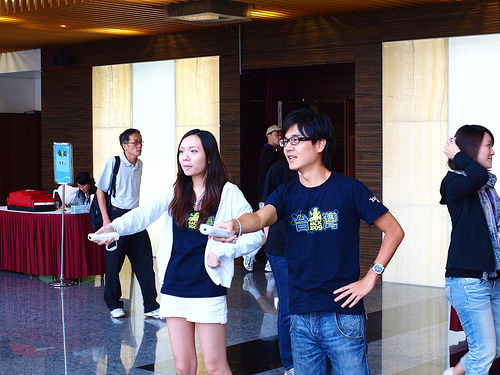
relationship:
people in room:
[59, 106, 499, 373] [2, 1, 500, 374]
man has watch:
[210, 106, 407, 373] [370, 260, 389, 274]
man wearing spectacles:
[210, 106, 407, 373] [281, 133, 326, 149]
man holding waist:
[210, 106, 407, 373] [282, 284, 372, 342]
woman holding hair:
[437, 125, 499, 373] [448, 125, 496, 173]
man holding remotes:
[210, 106, 407, 373] [199, 223, 237, 242]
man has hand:
[210, 106, 407, 373] [332, 271, 380, 311]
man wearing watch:
[210, 106, 407, 373] [370, 260, 389, 274]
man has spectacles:
[210, 106, 407, 373] [281, 133, 326, 149]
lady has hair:
[90, 130, 268, 374] [169, 129, 226, 230]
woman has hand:
[437, 125, 499, 373] [443, 136, 461, 160]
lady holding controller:
[84, 123, 270, 375] [87, 232, 124, 245]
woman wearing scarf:
[437, 125, 499, 373] [458, 166, 499, 274]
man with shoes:
[91, 130, 164, 323] [108, 308, 169, 318]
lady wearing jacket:
[84, 123, 270, 375] [109, 181, 265, 295]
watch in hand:
[370, 260, 389, 274] [332, 271, 380, 311]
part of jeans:
[347, 345, 354, 360] [287, 314, 373, 374]